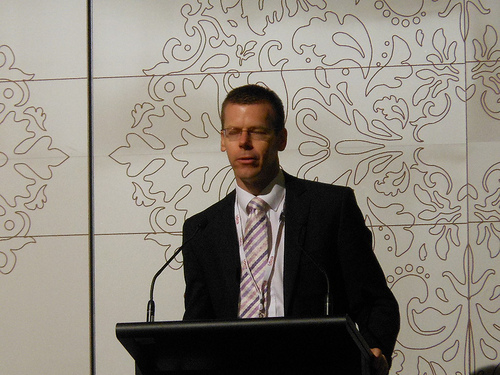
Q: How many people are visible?
A: 1.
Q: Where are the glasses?
A: Man's face.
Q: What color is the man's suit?
A: Black.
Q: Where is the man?
A: Behind podium.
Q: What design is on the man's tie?
A: Stripes.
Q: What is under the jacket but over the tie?
A: Vest.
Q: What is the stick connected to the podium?
A: Microphone.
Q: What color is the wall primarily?
A: White.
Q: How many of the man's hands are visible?
A: 1.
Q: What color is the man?
A: White.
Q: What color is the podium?
A: Black.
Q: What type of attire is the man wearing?
A: Suit.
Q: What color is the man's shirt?
A: White.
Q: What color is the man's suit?
A: Black.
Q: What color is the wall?
A: White.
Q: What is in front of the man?
A: A podium.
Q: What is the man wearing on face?
A: Glasses.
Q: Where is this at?
A: Indoors at meeting.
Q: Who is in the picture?
A: A man.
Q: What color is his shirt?
A: White.